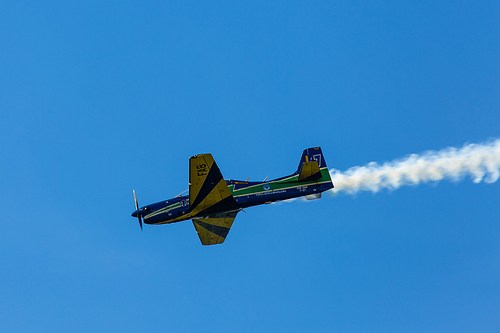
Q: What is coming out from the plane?
A: Smoke.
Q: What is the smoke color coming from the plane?
A: White.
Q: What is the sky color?
A: Clear blue.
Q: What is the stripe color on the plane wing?
A: Yellow and blue.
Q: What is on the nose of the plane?
A: Propeller.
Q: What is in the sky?
A: Airplane.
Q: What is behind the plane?
A: Exhaust.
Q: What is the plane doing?
A: Flying.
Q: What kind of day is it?
A: Clear.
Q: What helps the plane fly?
A: Wings.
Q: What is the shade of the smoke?
A: White.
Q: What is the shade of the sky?
A: Blue.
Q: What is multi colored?
A: The plane.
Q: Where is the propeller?
A: On the front of the plane.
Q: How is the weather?
A: Clear.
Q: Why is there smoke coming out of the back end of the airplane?
A: It is part of an airshow.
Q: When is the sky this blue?
A: On a sunny day.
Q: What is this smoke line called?
A: Contrails.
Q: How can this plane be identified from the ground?
A: By its stripes and numbers.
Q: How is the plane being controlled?
A: A pilot inside is operating it.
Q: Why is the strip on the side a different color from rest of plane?
A: To make it unique.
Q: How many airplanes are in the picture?
A: One.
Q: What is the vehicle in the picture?
A: Airplane.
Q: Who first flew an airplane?
A: Wright brothers.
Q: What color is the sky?
A: Blue.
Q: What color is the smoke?
A: White.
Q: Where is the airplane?
A: In the sky.